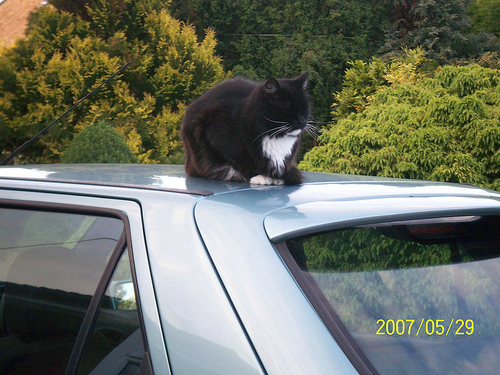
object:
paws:
[250, 174, 273, 185]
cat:
[180, 70, 336, 186]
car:
[0, 163, 499, 374]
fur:
[291, 129, 302, 136]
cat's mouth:
[290, 128, 306, 133]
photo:
[0, 0, 495, 372]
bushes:
[368, 69, 497, 153]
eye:
[282, 103, 296, 113]